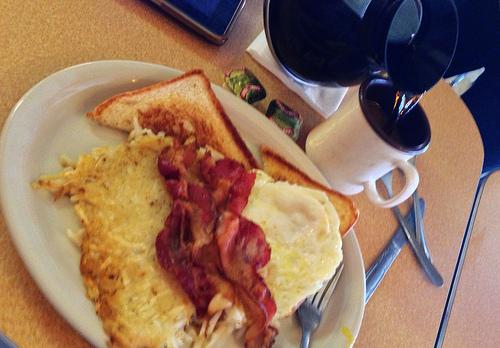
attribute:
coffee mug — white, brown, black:
[303, 77, 433, 209]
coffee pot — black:
[261, 0, 461, 94]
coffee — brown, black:
[389, 94, 422, 132]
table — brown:
[0, 0, 500, 347]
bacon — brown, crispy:
[157, 140, 220, 335]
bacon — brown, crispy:
[211, 155, 270, 347]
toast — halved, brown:
[89, 69, 256, 167]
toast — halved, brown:
[262, 148, 358, 234]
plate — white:
[2, 58, 366, 347]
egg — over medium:
[249, 172, 343, 316]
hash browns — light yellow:
[46, 132, 193, 347]